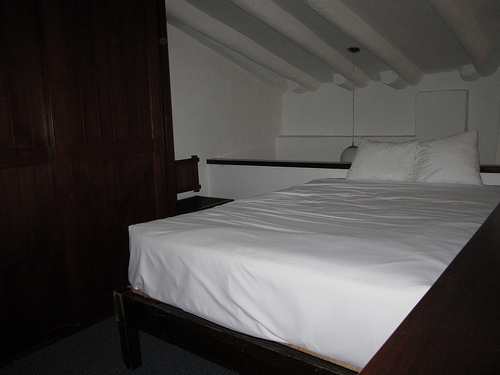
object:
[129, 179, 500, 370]
sheets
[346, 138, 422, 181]
pillow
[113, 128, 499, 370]
bed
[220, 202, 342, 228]
wrinkles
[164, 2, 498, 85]
ceiling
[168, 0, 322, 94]
light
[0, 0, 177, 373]
paneling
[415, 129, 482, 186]
pillow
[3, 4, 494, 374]
room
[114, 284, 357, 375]
bed frame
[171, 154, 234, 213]
chair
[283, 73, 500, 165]
wall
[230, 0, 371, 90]
light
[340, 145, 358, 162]
light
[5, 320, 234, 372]
carpet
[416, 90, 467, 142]
picture